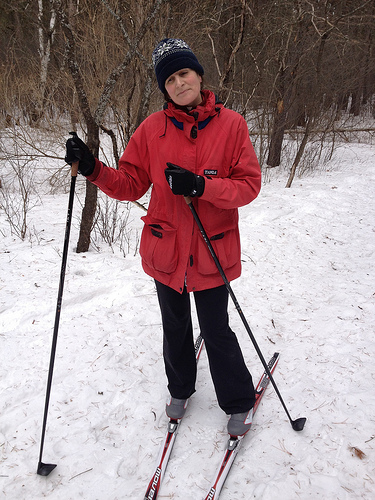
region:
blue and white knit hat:
[145, 31, 199, 79]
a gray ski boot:
[226, 411, 253, 436]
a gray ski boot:
[161, 395, 195, 426]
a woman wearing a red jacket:
[104, 32, 278, 442]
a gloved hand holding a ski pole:
[62, 125, 94, 180]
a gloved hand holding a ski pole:
[163, 161, 204, 201]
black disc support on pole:
[292, 412, 310, 432]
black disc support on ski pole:
[37, 460, 60, 477]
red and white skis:
[137, 430, 242, 498]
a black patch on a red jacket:
[203, 162, 215, 177]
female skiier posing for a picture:
[27, 35, 308, 498]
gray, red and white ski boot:
[161, 393, 201, 422]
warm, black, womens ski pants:
[147, 266, 257, 399]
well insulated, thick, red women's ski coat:
[95, 100, 271, 289]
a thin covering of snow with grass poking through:
[297, 219, 374, 433]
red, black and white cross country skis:
[138, 438, 241, 498]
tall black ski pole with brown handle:
[32, 128, 90, 483]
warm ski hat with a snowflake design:
[149, 43, 203, 75]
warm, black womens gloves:
[159, 164, 207, 197]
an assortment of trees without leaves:
[232, 20, 350, 192]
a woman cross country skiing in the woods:
[35, 34, 305, 497]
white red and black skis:
[143, 326, 282, 496]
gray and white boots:
[166, 395, 253, 433]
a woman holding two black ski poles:
[37, 132, 305, 476]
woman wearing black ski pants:
[154, 279, 257, 414]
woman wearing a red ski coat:
[87, 85, 264, 293]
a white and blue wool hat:
[151, 38, 204, 92]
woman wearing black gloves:
[63, 135, 202, 198]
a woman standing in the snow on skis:
[37, 37, 306, 498]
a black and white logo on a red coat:
[204, 168, 216, 177]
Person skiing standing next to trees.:
[32, 31, 308, 499]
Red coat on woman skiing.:
[59, 31, 274, 299]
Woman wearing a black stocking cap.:
[138, 30, 215, 110]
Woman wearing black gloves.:
[43, 114, 210, 215]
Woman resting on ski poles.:
[34, 35, 320, 498]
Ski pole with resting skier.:
[171, 183, 314, 438]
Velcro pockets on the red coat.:
[81, 88, 267, 296]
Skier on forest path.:
[0, 142, 371, 497]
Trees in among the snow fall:
[264, 0, 370, 172]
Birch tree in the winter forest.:
[19, 0, 69, 124]